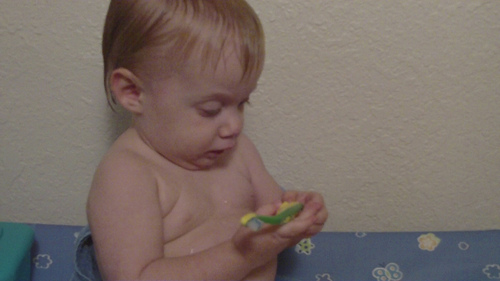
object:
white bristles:
[247, 218, 261, 232]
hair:
[103, 0, 267, 116]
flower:
[414, 232, 440, 253]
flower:
[480, 264, 498, 276]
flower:
[291, 237, 314, 256]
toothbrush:
[238, 201, 306, 232]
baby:
[85, 0, 329, 281]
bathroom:
[3, 0, 499, 279]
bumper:
[28, 222, 500, 278]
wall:
[1, 0, 498, 233]